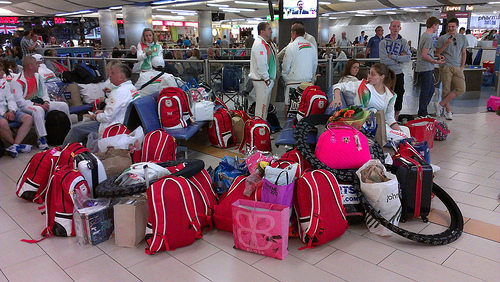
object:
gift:
[229, 192, 293, 264]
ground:
[190, 249, 303, 279]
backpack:
[144, 177, 209, 257]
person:
[439, 15, 471, 127]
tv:
[276, 0, 324, 23]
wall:
[276, 0, 325, 65]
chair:
[117, 73, 211, 140]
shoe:
[442, 105, 456, 123]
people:
[415, 14, 452, 127]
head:
[445, 17, 461, 36]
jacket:
[279, 39, 323, 86]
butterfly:
[232, 208, 278, 254]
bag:
[312, 121, 377, 172]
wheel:
[355, 160, 469, 246]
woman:
[342, 63, 420, 146]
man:
[98, 57, 141, 128]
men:
[252, 21, 282, 120]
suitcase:
[386, 148, 436, 221]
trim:
[166, 173, 205, 231]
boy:
[376, 18, 410, 101]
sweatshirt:
[378, 33, 411, 74]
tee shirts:
[414, 34, 438, 75]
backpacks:
[33, 163, 98, 242]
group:
[16, 143, 111, 240]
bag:
[353, 158, 403, 247]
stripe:
[397, 153, 426, 219]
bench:
[277, 111, 333, 155]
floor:
[443, 110, 498, 213]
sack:
[56, 83, 85, 108]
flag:
[0, 23, 21, 34]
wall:
[2, 12, 99, 49]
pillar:
[119, 5, 154, 54]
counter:
[470, 43, 499, 73]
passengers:
[437, 19, 463, 117]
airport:
[167, 1, 493, 271]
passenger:
[128, 23, 172, 78]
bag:
[131, 56, 157, 78]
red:
[168, 201, 189, 241]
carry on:
[157, 82, 197, 136]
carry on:
[241, 114, 277, 149]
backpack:
[292, 164, 352, 252]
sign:
[48, 13, 82, 28]